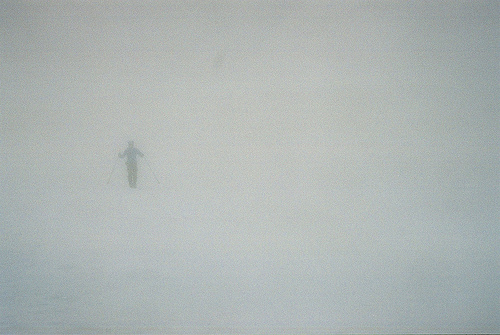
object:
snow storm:
[232, 66, 420, 216]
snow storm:
[204, 212, 376, 332]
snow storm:
[262, 227, 426, 332]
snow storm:
[339, 150, 497, 313]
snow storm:
[369, 17, 491, 145]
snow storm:
[111, 30, 226, 94]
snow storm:
[70, 27, 157, 98]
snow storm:
[20, 84, 85, 183]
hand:
[141, 154, 144, 159]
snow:
[0, 0, 500, 335]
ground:
[0, 0, 500, 335]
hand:
[118, 154, 122, 159]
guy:
[117, 140, 146, 189]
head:
[126, 140, 135, 149]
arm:
[135, 149, 144, 155]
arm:
[121, 150, 126, 158]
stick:
[141, 158, 158, 188]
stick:
[104, 156, 121, 185]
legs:
[127, 160, 139, 189]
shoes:
[129, 183, 138, 189]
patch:
[253, 229, 377, 280]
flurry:
[209, 25, 397, 128]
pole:
[107, 157, 121, 184]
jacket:
[117, 146, 144, 161]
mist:
[360, 278, 429, 316]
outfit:
[117, 140, 144, 189]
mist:
[0, 221, 118, 304]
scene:
[0, 0, 500, 335]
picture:
[0, 0, 500, 335]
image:
[0, 0, 500, 335]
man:
[118, 141, 147, 188]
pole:
[142, 157, 161, 186]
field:
[0, 0, 500, 334]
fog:
[224, 141, 303, 221]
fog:
[195, 189, 272, 261]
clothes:
[117, 140, 145, 189]